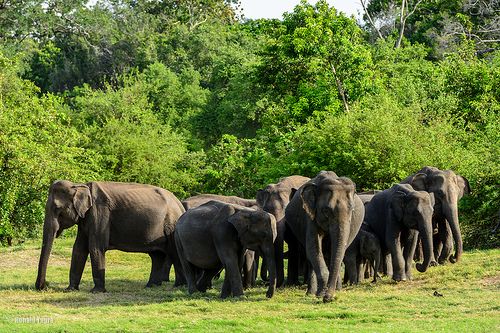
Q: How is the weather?
A: It is clear.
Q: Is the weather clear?
A: Yes, it is clear.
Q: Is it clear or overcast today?
A: It is clear.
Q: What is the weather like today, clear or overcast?
A: It is clear.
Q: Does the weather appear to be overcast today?
A: No, it is clear.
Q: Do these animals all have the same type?
A: Yes, all the animals are elephants.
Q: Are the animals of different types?
A: No, all the animals are elephants.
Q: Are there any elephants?
A: Yes, there is an elephant.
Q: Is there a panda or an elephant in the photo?
A: Yes, there is an elephant.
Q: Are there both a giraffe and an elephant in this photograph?
A: No, there is an elephant but no giraffes.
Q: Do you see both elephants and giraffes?
A: No, there is an elephant but no giraffes.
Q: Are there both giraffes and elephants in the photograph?
A: No, there is an elephant but no giraffes.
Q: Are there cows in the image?
A: No, there are no cows.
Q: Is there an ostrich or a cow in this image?
A: No, there are no cows or ostriches.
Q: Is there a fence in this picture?
A: No, there are no fences.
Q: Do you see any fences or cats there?
A: No, there are no fences or cats.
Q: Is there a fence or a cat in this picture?
A: No, there are no fences or cats.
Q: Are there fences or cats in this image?
A: No, there are no fences or cats.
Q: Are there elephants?
A: Yes, there is an elephant.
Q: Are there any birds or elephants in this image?
A: Yes, there is an elephant.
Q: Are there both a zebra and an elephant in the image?
A: No, there is an elephant but no zebras.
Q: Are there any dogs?
A: No, there are no dogs.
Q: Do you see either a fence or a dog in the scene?
A: No, there are no dogs or fences.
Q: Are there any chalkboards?
A: No, there are no chalkboards.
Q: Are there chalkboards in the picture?
A: No, there are no chalkboards.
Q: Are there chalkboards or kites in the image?
A: No, there are no chalkboards or kites.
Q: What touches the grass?
A: The trunk touches the grass.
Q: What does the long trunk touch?
A: The trunk touches the grass.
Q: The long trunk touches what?
A: The trunk touches the grass.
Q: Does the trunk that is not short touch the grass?
A: Yes, the trunk touches the grass.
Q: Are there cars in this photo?
A: No, there are no cars.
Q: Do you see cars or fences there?
A: No, there are no cars or fences.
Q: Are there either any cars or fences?
A: No, there are no cars or fences.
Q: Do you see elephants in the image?
A: Yes, there is an elephant.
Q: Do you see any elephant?
A: Yes, there is an elephant.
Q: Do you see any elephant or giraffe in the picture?
A: Yes, there is an elephant.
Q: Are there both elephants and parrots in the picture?
A: No, there is an elephant but no parrots.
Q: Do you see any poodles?
A: No, there are no poodles.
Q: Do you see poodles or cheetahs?
A: No, there are no poodles or cheetahs.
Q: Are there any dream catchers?
A: No, there are no dream catchers.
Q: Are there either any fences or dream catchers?
A: No, there are no dream catchers or fences.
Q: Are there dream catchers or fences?
A: No, there are no dream catchers or fences.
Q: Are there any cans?
A: No, there are no cans.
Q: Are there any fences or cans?
A: No, there are no cans or fences.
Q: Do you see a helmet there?
A: No, there are no helmets.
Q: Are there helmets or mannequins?
A: No, there are no helmets or mannequins.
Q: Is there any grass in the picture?
A: Yes, there is grass.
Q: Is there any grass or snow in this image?
A: Yes, there is grass.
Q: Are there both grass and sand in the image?
A: No, there is grass but no sand.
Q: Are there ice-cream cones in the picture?
A: No, there are no ice-cream cones.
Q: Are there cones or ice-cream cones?
A: No, there are no ice-cream cones or cones.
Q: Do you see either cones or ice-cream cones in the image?
A: No, there are no ice-cream cones or cones.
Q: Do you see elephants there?
A: Yes, there is an elephant.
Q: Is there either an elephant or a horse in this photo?
A: Yes, there is an elephant.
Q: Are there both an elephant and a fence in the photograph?
A: No, there is an elephant but no fences.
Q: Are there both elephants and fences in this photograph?
A: No, there is an elephant but no fences.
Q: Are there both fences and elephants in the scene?
A: No, there is an elephant but no fences.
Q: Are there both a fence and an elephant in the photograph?
A: No, there is an elephant but no fences.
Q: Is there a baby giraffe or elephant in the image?
A: Yes, there is a baby elephant.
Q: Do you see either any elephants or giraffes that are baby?
A: Yes, the elephant is a baby.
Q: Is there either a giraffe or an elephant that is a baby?
A: Yes, the elephant is a baby.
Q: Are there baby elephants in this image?
A: Yes, there is a baby elephant.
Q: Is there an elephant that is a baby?
A: Yes, there is an elephant that is a baby.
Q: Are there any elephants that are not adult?
A: Yes, there is an baby elephant.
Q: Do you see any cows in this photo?
A: No, there are no cows.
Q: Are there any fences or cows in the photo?
A: No, there are no cows or fences.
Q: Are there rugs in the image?
A: No, there are no rugs.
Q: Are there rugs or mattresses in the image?
A: No, there are no rugs or mattresses.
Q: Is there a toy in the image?
A: No, there are no toys.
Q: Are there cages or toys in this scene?
A: No, there are no toys or cages.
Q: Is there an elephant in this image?
A: Yes, there is an elephant.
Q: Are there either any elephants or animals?
A: Yes, there is an elephant.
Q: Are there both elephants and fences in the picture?
A: No, there is an elephant but no fences.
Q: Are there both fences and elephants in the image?
A: No, there is an elephant but no fences.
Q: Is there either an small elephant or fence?
A: Yes, there is a small elephant.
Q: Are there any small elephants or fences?
A: Yes, there is a small elephant.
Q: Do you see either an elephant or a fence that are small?
A: Yes, the elephant is small.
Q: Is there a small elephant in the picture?
A: Yes, there is a small elephant.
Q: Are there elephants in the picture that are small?
A: Yes, there is an elephant that is small.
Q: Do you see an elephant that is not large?
A: Yes, there is a small elephant.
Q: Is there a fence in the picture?
A: No, there are no fences.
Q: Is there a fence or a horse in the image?
A: No, there are no fences or horses.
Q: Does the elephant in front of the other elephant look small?
A: Yes, the elephant is small.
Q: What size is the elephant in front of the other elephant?
A: The elephant is small.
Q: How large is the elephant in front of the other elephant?
A: The elephant is small.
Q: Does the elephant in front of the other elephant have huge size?
A: No, the elephant is small.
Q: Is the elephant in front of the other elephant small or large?
A: The elephant is small.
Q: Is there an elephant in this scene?
A: Yes, there is an elephant.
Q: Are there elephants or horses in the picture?
A: Yes, there is an elephant.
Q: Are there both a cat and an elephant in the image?
A: No, there is an elephant but no cats.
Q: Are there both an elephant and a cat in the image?
A: No, there is an elephant but no cats.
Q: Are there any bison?
A: No, there are no bison.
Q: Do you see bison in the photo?
A: No, there are no bison.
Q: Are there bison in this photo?
A: No, there are no bison.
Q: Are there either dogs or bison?
A: No, there are no bison or dogs.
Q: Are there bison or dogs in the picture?
A: No, there are no bison or dogs.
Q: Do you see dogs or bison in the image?
A: No, there are no bison or dogs.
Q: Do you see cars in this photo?
A: No, there are no cars.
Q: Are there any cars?
A: No, there are no cars.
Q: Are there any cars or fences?
A: No, there are no cars or fences.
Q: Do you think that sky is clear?
A: Yes, the sky is clear.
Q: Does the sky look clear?
A: Yes, the sky is clear.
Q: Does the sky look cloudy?
A: No, the sky is clear.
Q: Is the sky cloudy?
A: No, the sky is clear.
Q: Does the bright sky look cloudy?
A: No, the sky is clear.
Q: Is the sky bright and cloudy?
A: No, the sky is bright but clear.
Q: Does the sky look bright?
A: Yes, the sky is bright.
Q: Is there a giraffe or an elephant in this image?
A: Yes, there are elephants.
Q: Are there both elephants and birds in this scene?
A: No, there are elephants but no birds.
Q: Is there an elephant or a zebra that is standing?
A: Yes, the elephants are standing.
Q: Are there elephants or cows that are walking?
A: Yes, the elephants are walking.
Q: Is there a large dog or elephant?
A: Yes, there are large elephants.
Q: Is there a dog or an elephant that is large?
A: Yes, the elephants are large.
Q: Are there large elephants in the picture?
A: Yes, there are large elephants.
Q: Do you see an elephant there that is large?
A: Yes, there are elephants that are large.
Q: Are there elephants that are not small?
A: Yes, there are large elephants.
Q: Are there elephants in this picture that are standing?
A: Yes, there are elephants that are standing.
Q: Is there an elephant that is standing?
A: Yes, there are elephants that are standing.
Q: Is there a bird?
A: No, there are no birds.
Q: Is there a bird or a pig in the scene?
A: No, there are no birds or pigs.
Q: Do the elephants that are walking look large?
A: Yes, the elephants are large.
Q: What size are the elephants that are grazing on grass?
A: The elephants are large.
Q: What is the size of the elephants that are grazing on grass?
A: The elephants are large.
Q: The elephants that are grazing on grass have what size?
A: The elephants are large.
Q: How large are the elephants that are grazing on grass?
A: The elephants are large.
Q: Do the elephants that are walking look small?
A: No, the elephants are large.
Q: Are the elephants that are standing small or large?
A: The elephants are large.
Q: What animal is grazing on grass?
A: The elephants are grazing on grass.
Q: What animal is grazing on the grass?
A: The elephants are grazing on grass.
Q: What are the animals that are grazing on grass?
A: The animals are elephants.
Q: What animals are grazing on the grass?
A: The animals are elephants.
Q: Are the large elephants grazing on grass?
A: Yes, the elephants are grazing on grass.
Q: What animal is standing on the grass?
A: The elephants are standing on the grass.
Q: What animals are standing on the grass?
A: The animals are elephants.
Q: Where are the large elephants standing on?
A: The elephants are standing on the grass.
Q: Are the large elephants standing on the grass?
A: Yes, the elephants are standing on the grass.